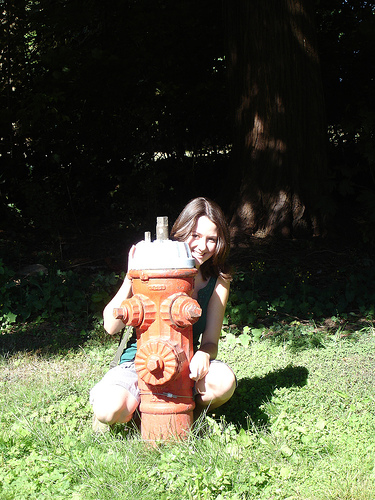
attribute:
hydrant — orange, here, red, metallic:
[110, 215, 203, 446]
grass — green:
[2, 281, 371, 499]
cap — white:
[129, 216, 198, 274]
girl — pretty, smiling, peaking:
[88, 193, 240, 435]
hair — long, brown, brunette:
[170, 196, 235, 285]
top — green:
[119, 268, 220, 362]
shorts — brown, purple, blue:
[110, 351, 215, 399]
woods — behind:
[3, 2, 374, 277]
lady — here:
[88, 194, 240, 436]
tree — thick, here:
[76, 2, 342, 253]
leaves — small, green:
[0, 0, 370, 180]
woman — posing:
[88, 197, 238, 438]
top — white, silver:
[126, 215, 194, 271]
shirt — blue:
[116, 271, 219, 364]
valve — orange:
[133, 339, 182, 392]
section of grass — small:
[35, 392, 262, 478]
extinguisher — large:
[114, 213, 203, 446]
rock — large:
[17, 263, 49, 279]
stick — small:
[251, 307, 303, 339]